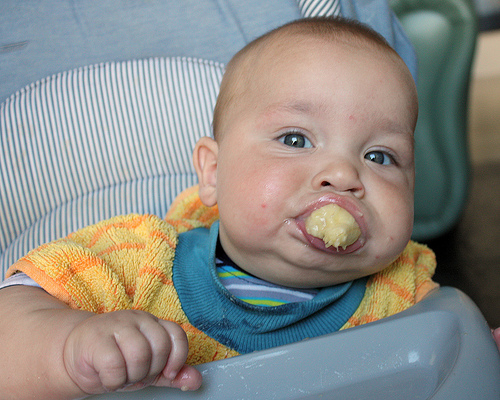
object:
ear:
[193, 136, 218, 207]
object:
[79, 285, 499, 398]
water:
[284, 216, 310, 225]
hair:
[212, 15, 391, 141]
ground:
[470, 170, 500, 226]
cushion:
[0, 56, 227, 280]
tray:
[428, 279, 440, 391]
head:
[193, 16, 418, 289]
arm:
[0, 286, 59, 397]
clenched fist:
[68, 310, 202, 395]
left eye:
[364, 151, 391, 166]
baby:
[0, 15, 419, 400]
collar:
[173, 219, 371, 354]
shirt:
[0, 234, 323, 307]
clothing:
[0, 184, 440, 367]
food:
[305, 203, 361, 252]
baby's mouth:
[286, 192, 367, 254]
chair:
[0, 3, 499, 400]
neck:
[220, 226, 365, 289]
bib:
[4, 185, 440, 369]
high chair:
[0, 0, 491, 400]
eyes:
[277, 133, 316, 148]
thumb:
[156, 364, 202, 390]